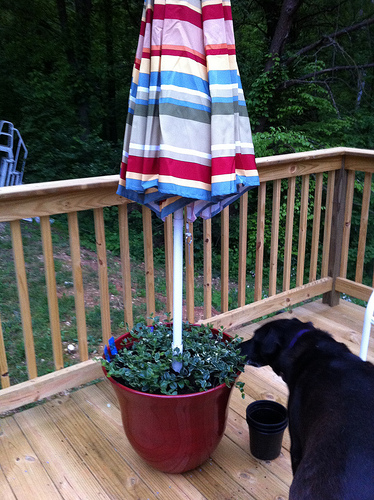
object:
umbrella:
[116, 1, 262, 222]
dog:
[240, 319, 371, 499]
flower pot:
[99, 322, 247, 476]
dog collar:
[275, 325, 330, 379]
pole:
[173, 163, 185, 367]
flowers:
[99, 334, 123, 368]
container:
[245, 398, 291, 463]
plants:
[100, 303, 253, 399]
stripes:
[127, 11, 242, 182]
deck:
[4, 149, 372, 495]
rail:
[0, 147, 371, 407]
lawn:
[9, 141, 371, 374]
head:
[236, 319, 314, 374]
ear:
[256, 327, 286, 360]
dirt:
[0, 237, 251, 331]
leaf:
[239, 385, 247, 399]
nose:
[233, 336, 254, 361]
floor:
[0, 298, 371, 499]